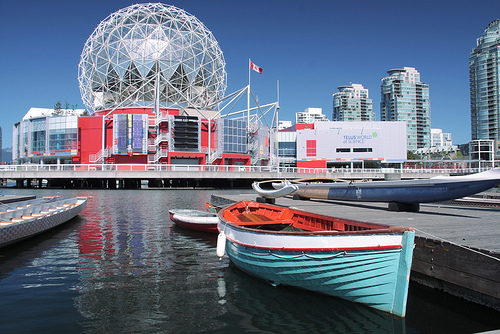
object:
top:
[380, 65, 429, 94]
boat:
[215, 199, 416, 318]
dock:
[206, 188, 500, 308]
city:
[2, 2, 500, 171]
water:
[1, 237, 218, 334]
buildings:
[297, 106, 326, 125]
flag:
[250, 60, 265, 74]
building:
[10, 102, 267, 165]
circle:
[77, 3, 229, 109]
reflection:
[70, 192, 170, 265]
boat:
[272, 168, 500, 203]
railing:
[1, 162, 491, 174]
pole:
[247, 58, 252, 135]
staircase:
[88, 147, 113, 164]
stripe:
[255, 259, 348, 269]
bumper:
[172, 216, 220, 224]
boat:
[0, 194, 91, 245]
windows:
[49, 134, 57, 139]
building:
[470, 16, 499, 139]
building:
[380, 64, 433, 152]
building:
[331, 81, 375, 119]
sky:
[254, 1, 471, 66]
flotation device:
[216, 229, 227, 260]